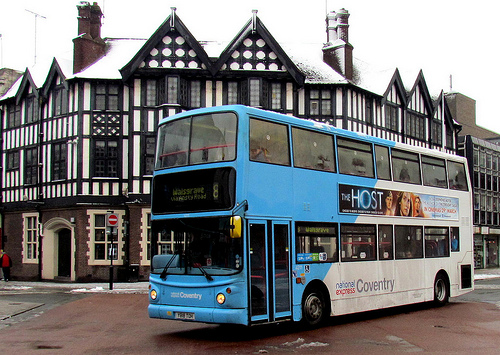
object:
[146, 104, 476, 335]
bus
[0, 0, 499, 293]
house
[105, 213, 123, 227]
sign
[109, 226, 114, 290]
pole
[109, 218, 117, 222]
white dash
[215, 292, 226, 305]
headlights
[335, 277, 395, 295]
name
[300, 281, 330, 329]
black tires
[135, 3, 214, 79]
gables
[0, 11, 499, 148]
roof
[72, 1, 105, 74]
chimney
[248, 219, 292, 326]
door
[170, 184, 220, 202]
electric sign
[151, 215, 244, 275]
windshield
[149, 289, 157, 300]
left headlight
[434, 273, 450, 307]
rear tire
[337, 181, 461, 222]
ad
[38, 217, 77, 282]
archway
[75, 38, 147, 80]
snow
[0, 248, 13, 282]
person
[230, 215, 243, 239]
mirror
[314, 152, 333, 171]
people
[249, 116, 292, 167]
window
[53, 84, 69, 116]
window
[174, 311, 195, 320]
license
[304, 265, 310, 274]
handicap sticker